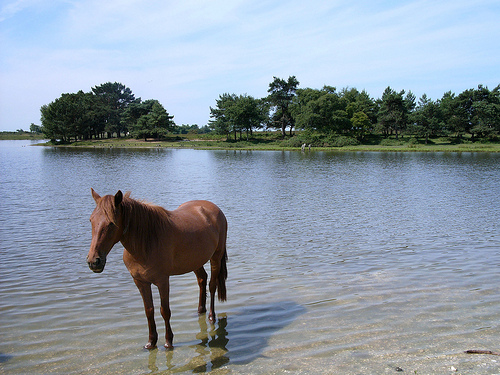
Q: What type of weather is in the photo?
A: It is cloudless.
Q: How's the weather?
A: It is cloudless.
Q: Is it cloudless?
A: Yes, it is cloudless.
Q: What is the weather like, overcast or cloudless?
A: It is cloudless.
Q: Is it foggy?
A: No, it is cloudless.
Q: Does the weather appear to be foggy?
A: No, it is cloudless.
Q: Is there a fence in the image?
A: No, there are no fences.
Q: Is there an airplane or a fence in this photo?
A: No, there are no fences or airplanes.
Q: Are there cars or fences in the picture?
A: No, there are no cars or fences.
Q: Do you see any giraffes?
A: No, there are no giraffes.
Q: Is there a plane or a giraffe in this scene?
A: No, there are no giraffes or airplanes.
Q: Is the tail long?
A: Yes, the tail is long.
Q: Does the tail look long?
A: Yes, the tail is long.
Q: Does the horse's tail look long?
A: Yes, the tail is long.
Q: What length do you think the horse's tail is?
A: The tail is long.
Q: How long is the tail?
A: The tail is long.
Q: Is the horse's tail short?
A: No, the tail is long.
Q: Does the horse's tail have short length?
A: No, the tail is long.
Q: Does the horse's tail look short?
A: No, the tail is long.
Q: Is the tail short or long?
A: The tail is long.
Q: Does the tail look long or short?
A: The tail is long.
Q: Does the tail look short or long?
A: The tail is long.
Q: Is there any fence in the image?
A: No, there are no fences.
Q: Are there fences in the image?
A: No, there are no fences.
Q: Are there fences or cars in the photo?
A: No, there are no fences or cars.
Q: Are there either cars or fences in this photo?
A: No, there are no fences or cars.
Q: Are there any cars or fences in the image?
A: No, there are no cars or fences.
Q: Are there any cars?
A: No, there are no cars.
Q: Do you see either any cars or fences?
A: No, there are no cars or fences.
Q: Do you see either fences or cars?
A: No, there are no cars or fences.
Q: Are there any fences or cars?
A: No, there are no cars or fences.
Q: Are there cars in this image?
A: No, there are no cars.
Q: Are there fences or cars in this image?
A: No, there are no cars or fences.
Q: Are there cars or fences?
A: No, there are no cars or fences.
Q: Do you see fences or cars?
A: No, there are no cars or fences.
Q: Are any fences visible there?
A: No, there are no fences.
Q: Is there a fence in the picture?
A: No, there are no fences.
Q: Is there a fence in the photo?
A: No, there are no fences.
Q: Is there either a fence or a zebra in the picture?
A: No, there are no fences or zebras.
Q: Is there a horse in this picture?
A: Yes, there is a horse.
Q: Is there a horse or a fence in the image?
A: Yes, there is a horse.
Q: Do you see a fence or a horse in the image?
A: Yes, there is a horse.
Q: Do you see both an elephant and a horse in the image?
A: No, there is a horse but no elephants.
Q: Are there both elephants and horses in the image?
A: No, there is a horse but no elephants.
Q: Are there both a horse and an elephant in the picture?
A: No, there is a horse but no elephants.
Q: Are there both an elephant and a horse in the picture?
A: No, there is a horse but no elephants.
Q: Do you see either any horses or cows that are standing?
A: Yes, the horse is standing.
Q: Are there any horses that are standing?
A: Yes, there is a horse that is standing.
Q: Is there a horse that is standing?
A: Yes, there is a horse that is standing.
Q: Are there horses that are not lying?
A: Yes, there is a horse that is standing.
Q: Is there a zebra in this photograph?
A: No, there are no zebras.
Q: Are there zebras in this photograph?
A: No, there are no zebras.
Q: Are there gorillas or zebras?
A: No, there are no zebras or gorillas.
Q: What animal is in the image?
A: The animal is a horse.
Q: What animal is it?
A: The animal is a horse.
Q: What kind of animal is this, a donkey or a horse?
A: That is a horse.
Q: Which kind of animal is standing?
A: The animal is a horse.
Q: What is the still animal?
A: The animal is a horse.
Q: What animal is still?
A: The animal is a horse.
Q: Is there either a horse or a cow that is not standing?
A: No, there is a horse but it is standing.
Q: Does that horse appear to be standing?
A: Yes, the horse is standing.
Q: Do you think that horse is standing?
A: Yes, the horse is standing.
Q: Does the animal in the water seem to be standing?
A: Yes, the horse is standing.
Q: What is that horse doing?
A: The horse is standing.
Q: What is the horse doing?
A: The horse is standing.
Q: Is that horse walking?
A: No, the horse is standing.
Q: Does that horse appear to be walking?
A: No, the horse is standing.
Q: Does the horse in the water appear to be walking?
A: No, the horse is standing.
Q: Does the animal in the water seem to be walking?
A: No, the horse is standing.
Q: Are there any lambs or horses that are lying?
A: No, there is a horse but it is standing.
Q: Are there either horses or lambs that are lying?
A: No, there is a horse but it is standing.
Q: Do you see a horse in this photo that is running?
A: No, there is a horse but it is standing.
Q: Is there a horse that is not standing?
A: No, there is a horse but it is standing.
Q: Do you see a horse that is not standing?
A: No, there is a horse but it is standing.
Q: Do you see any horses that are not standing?
A: No, there is a horse but it is standing.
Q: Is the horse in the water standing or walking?
A: The horse is standing.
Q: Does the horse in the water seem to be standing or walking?
A: The horse is standing.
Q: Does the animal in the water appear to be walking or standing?
A: The horse is standing.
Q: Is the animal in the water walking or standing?
A: The horse is standing.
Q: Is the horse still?
A: Yes, the horse is still.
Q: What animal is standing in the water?
A: The horse is standing in the water.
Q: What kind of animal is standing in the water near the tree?
A: The animal is a horse.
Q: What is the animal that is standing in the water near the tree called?
A: The animal is a horse.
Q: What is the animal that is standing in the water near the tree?
A: The animal is a horse.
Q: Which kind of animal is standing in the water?
A: The animal is a horse.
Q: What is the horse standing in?
A: The horse is standing in the water.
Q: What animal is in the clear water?
A: The horse is in the water.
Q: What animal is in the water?
A: The horse is in the water.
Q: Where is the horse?
A: The horse is in the water.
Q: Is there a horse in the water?
A: Yes, there is a horse in the water.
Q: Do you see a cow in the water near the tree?
A: No, there is a horse in the water.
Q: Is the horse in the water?
A: Yes, the horse is in the water.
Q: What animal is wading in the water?
A: The horse is wading in the water.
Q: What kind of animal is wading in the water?
A: The animal is a horse.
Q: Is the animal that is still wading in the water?
A: Yes, the horse is wading in the water.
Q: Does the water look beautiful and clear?
A: Yes, the water is beautiful and clear.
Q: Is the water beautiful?
A: Yes, the water is beautiful.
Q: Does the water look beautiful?
A: Yes, the water is beautiful.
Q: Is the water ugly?
A: No, the water is beautiful.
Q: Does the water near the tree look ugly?
A: No, the water is beautiful.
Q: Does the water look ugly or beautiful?
A: The water is beautiful.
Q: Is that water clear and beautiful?
A: Yes, the water is clear and beautiful.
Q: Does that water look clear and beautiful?
A: Yes, the water is clear and beautiful.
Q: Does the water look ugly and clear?
A: No, the water is clear but beautiful.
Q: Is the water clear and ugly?
A: No, the water is clear but beautiful.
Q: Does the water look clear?
A: Yes, the water is clear.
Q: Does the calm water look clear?
A: Yes, the water is clear.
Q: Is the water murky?
A: No, the water is clear.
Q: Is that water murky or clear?
A: The water is clear.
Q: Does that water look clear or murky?
A: The water is clear.